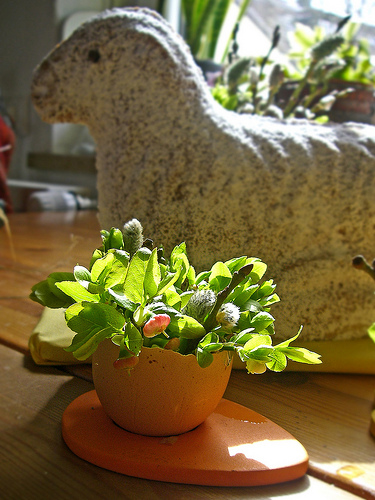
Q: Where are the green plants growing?
A: In a planter.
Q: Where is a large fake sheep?
A: On the table.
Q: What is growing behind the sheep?
A: Plants.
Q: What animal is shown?
A: A lamb.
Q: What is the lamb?
A: Sculpture.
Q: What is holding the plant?
A: Clay pot.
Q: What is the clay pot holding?
A: Flowers.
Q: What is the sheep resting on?
A: Yellow pedestal.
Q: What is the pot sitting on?
A: Pedestal.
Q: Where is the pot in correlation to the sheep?
A: In front of it.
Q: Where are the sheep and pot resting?
A: A table.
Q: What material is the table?
A: Wood.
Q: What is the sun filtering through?
A: A window.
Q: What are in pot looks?
A: Flowers.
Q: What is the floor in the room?
A: Hardwood.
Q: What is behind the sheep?
A: Window.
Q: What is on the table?
A: Cement table.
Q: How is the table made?
A: Wood.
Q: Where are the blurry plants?
A: In the window.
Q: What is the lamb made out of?
A: Concrete.